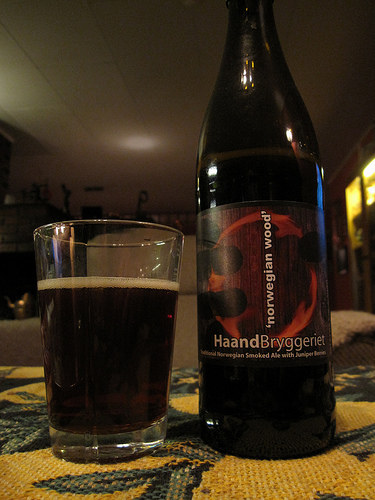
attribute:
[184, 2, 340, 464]
bottle — ale, norwegian, dark, dark colored, large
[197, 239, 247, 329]
berry — design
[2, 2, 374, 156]
ceiling tiles — white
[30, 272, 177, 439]
liquid — brown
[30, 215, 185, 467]
glass — clear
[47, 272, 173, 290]
head — white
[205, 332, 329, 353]
writing — white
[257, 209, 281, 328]
writing — white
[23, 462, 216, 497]
coloring — blue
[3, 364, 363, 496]
place mat — yellow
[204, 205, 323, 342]
coloring — red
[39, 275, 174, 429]
liquid — dark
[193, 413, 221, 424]
glare — light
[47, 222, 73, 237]
glare — light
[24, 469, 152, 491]
leaf — blue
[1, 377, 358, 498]
background — yellow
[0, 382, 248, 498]
pattern — blue, yellow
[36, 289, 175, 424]
ale — top 